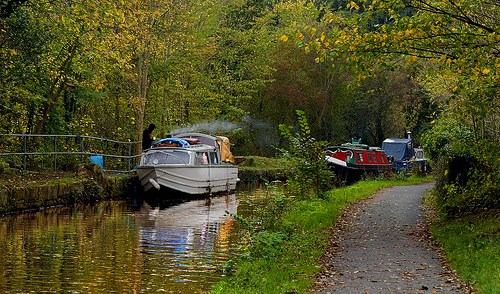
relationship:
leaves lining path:
[410, 209, 469, 281] [317, 171, 482, 292]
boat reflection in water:
[139, 190, 241, 257] [0, 171, 277, 291]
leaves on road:
[348, 218, 430, 275] [310, 175, 463, 291]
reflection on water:
[150, 189, 239, 228] [64, 212, 179, 292]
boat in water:
[131, 131, 245, 199] [0, 166, 342, 292]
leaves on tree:
[173, 34, 278, 77] [5, 4, 290, 151]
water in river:
[58, 215, 183, 289] [16, 141, 313, 289]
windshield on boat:
[139, 150, 192, 166] [131, 131, 245, 199]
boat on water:
[131, 131, 245, 199] [2, 190, 247, 291]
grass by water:
[209, 163, 431, 292] [0, 166, 342, 292]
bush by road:
[264, 92, 389, 239] [310, 175, 463, 291]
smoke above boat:
[164, 114, 256, 139] [131, 131, 245, 199]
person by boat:
[142, 123, 156, 152] [131, 131, 245, 199]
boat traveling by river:
[136, 133, 241, 197] [0, 180, 292, 292]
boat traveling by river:
[318, 136, 389, 185] [0, 180, 292, 292]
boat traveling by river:
[377, 127, 434, 177] [0, 180, 292, 292]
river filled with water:
[0, 166, 289, 292] [0, 180, 297, 292]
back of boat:
[215, 140, 244, 179] [136, 109, 268, 196]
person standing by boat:
[137, 122, 158, 150] [131, 131, 245, 199]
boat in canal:
[136, 133, 241, 197] [4, 192, 281, 291]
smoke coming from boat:
[164, 107, 255, 139] [135, 122, 248, 196]